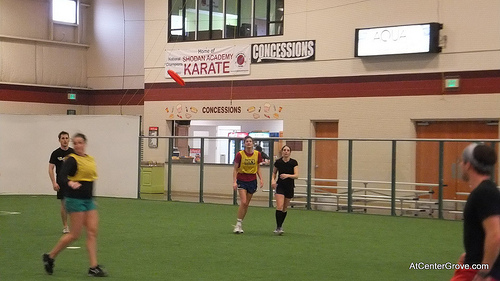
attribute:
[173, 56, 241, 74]
sign — red, white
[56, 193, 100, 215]
shorts — blue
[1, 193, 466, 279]
floor — GREEN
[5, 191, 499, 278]
floor — green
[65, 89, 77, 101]
exit sign — gray, green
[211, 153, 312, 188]
yello shirt — yellow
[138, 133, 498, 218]
fence — metal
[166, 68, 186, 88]
frisbee — red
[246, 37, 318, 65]
sign — black and white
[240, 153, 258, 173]
tank top — yellow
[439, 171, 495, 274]
shirt — black